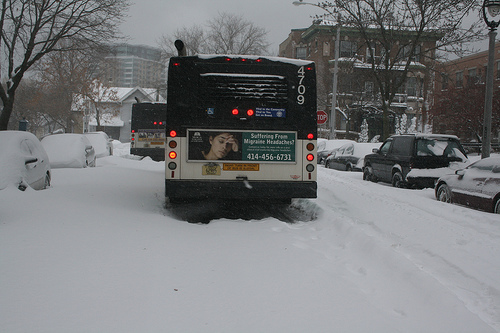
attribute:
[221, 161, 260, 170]
license plate — yellow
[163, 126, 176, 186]
light — of bus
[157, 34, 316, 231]
bus —  The back 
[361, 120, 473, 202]
car — black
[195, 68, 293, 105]
bus vent — of bus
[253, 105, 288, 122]
sign — blue